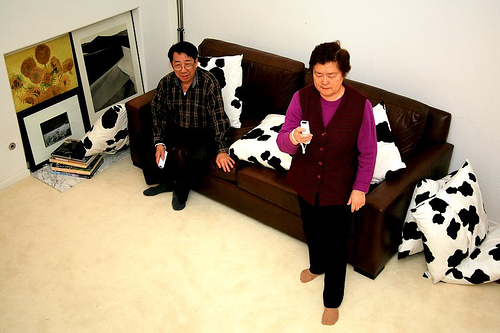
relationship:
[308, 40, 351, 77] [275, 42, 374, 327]
hair of a man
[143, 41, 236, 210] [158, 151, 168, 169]
man holds controller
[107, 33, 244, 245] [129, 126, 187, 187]
man holding controller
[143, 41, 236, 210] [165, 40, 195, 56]
man with hair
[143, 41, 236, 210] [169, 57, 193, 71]
man with glasses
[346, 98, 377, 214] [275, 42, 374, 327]
arm on man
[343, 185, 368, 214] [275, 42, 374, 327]
hand on man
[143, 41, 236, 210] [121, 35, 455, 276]
man on couch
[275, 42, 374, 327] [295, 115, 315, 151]
man holding game control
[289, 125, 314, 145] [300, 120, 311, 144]
hand holding cellphone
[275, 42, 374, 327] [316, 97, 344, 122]
man wearing top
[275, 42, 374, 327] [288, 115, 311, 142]
man holding cellphone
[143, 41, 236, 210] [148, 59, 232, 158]
man wearing shirt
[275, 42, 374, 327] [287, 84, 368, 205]
man wearing shirt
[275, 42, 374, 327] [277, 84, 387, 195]
man wearing shirt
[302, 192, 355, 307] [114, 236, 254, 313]
pants on floor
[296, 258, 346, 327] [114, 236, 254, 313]
feet on floor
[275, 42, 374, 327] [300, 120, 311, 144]
man holding cellphone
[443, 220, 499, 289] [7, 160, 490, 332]
cow pillows on floor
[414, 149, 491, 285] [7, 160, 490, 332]
cow pillows on floor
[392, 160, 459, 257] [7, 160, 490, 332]
cow pillows on floor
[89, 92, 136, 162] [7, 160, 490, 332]
cow pillows on floor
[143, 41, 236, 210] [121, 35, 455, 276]
man sitting on couch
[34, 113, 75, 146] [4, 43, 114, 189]
photo in black frame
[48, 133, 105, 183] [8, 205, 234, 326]
books on ground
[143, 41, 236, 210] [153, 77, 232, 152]
man wearing plaid shirt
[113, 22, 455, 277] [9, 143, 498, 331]
sofa on carpet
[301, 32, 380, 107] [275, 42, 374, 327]
head of a man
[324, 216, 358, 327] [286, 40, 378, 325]
leg of a person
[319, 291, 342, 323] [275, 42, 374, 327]
foot of a man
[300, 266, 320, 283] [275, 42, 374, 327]
foot of a man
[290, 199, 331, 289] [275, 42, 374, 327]
leg of a man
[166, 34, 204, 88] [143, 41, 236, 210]
head of a man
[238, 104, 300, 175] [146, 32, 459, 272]
cushion on couch